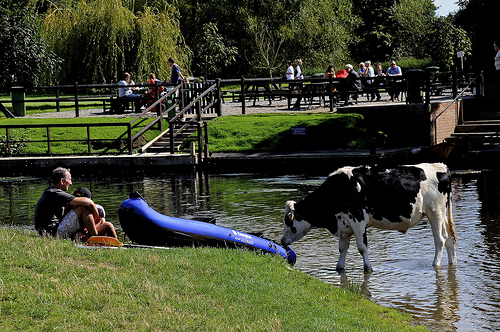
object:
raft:
[117, 190, 296, 271]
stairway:
[136, 117, 217, 154]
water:
[0, 172, 500, 332]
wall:
[414, 99, 474, 148]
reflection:
[391, 260, 436, 271]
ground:
[393, 212, 427, 243]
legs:
[336, 214, 375, 273]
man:
[34, 166, 100, 239]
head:
[280, 198, 317, 247]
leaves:
[32, 17, 81, 48]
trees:
[241, 16, 286, 79]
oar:
[75, 236, 172, 250]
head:
[50, 167, 72, 192]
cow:
[281, 162, 456, 274]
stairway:
[428, 73, 498, 155]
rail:
[425, 68, 485, 145]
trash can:
[10, 85, 28, 117]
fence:
[0, 122, 133, 157]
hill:
[15, 107, 460, 156]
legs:
[424, 203, 459, 267]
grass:
[0, 221, 432, 332]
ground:
[18, 216, 409, 328]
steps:
[146, 115, 218, 156]